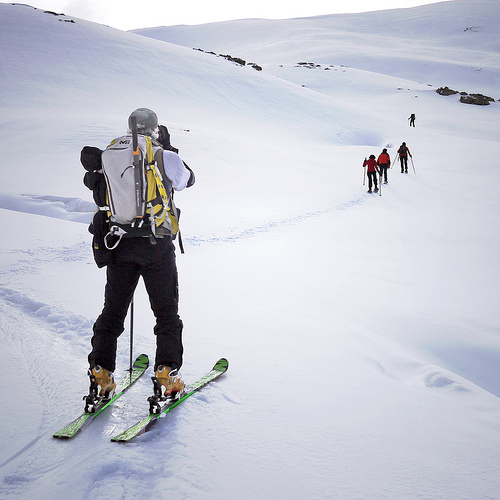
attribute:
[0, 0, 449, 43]
sky — bright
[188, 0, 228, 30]
sky — white, featurless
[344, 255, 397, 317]
snow — white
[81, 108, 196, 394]
man — stopped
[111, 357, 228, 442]
skis — Green and black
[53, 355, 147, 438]
skis — Green and black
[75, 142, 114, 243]
packs — Three, black, down man's side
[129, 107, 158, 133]
cap — grey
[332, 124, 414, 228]
trail — snowy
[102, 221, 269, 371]
pants — black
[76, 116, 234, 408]
skier — stopped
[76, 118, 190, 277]
backpack — alpine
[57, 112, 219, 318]
gear — climbing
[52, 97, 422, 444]
people — snowskating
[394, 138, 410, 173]
person — walking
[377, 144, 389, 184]
person — walking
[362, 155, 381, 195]
person — walking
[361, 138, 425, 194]
people — some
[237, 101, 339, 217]
snow — ridges, on the ascent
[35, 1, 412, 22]
sky — full of clouds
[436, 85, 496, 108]
outcropping — rocky, bare